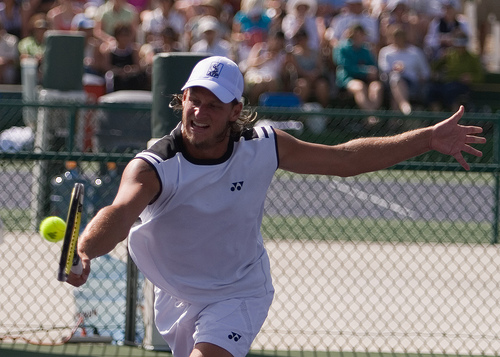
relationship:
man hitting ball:
[67, 55, 484, 356] [38, 217, 67, 242]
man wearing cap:
[67, 55, 484, 356] [180, 54, 243, 105]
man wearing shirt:
[67, 55, 484, 356] [129, 123, 276, 301]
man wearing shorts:
[67, 55, 484, 356] [153, 287, 275, 356]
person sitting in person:
[335, 23, 383, 129] [330, 23, 384, 124]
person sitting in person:
[379, 25, 433, 122] [330, 23, 384, 124]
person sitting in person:
[290, 32, 331, 103] [330, 23, 384, 124]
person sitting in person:
[241, 31, 290, 104] [330, 23, 384, 124]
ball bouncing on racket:
[38, 217, 67, 242] [56, 181, 85, 280]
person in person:
[290, 32, 331, 103] [330, 23, 384, 124]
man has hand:
[67, 55, 484, 356] [433, 105, 487, 173]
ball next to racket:
[38, 217, 67, 242] [56, 181, 85, 280]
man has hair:
[67, 55, 484, 356] [168, 93, 258, 135]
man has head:
[67, 55, 484, 356] [180, 55, 245, 147]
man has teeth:
[67, 55, 484, 356] [190, 122, 213, 130]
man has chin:
[67, 55, 484, 356] [189, 131, 208, 147]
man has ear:
[67, 55, 484, 356] [229, 102, 243, 122]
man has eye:
[67, 55, 484, 356] [190, 98, 200, 105]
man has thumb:
[67, 55, 484, 356] [449, 104, 465, 124]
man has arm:
[67, 55, 484, 356] [271, 125, 435, 176]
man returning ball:
[67, 55, 484, 356] [38, 217, 67, 242]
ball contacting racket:
[38, 217, 67, 242] [56, 181, 85, 280]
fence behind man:
[1, 153, 499, 356] [67, 55, 484, 356]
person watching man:
[330, 23, 384, 124] [67, 55, 484, 356]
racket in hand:
[56, 181, 85, 280] [67, 254, 91, 287]